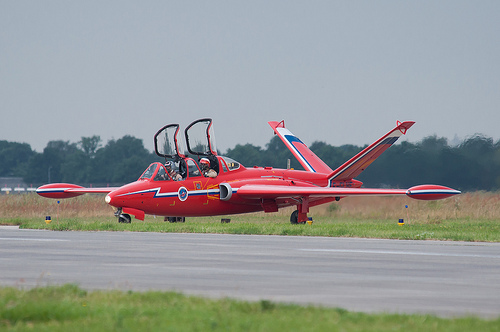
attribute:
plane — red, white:
[0, 105, 461, 210]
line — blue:
[189, 185, 205, 206]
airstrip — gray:
[141, 237, 203, 254]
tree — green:
[66, 152, 98, 166]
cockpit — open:
[151, 119, 180, 185]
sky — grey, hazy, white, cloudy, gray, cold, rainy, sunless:
[149, 14, 186, 43]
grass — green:
[45, 292, 80, 313]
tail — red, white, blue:
[259, 113, 417, 172]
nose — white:
[96, 181, 130, 218]